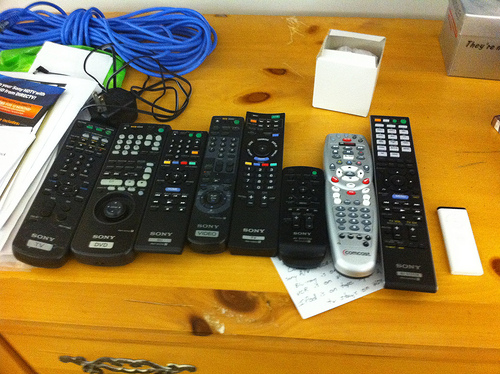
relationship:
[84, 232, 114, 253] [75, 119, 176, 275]
sony on a remote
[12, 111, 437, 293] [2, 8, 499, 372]
control on table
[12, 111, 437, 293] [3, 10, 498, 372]
control on top of dresser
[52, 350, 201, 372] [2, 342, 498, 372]
handle on drawer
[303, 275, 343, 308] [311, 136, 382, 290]
note under remote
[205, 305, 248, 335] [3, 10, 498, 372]
paint on dresser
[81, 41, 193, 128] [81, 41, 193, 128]
charger has charger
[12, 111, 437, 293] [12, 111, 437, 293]
control together with control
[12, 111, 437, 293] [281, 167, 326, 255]
control together with remote control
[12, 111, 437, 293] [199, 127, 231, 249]
control together with remote control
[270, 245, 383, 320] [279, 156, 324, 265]
paper under remote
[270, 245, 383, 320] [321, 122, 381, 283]
paper under remote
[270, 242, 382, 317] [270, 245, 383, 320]
paper has paper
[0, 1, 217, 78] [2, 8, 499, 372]
blue wires on table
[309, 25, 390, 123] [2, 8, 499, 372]
box on table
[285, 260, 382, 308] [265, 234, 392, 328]
note on paper